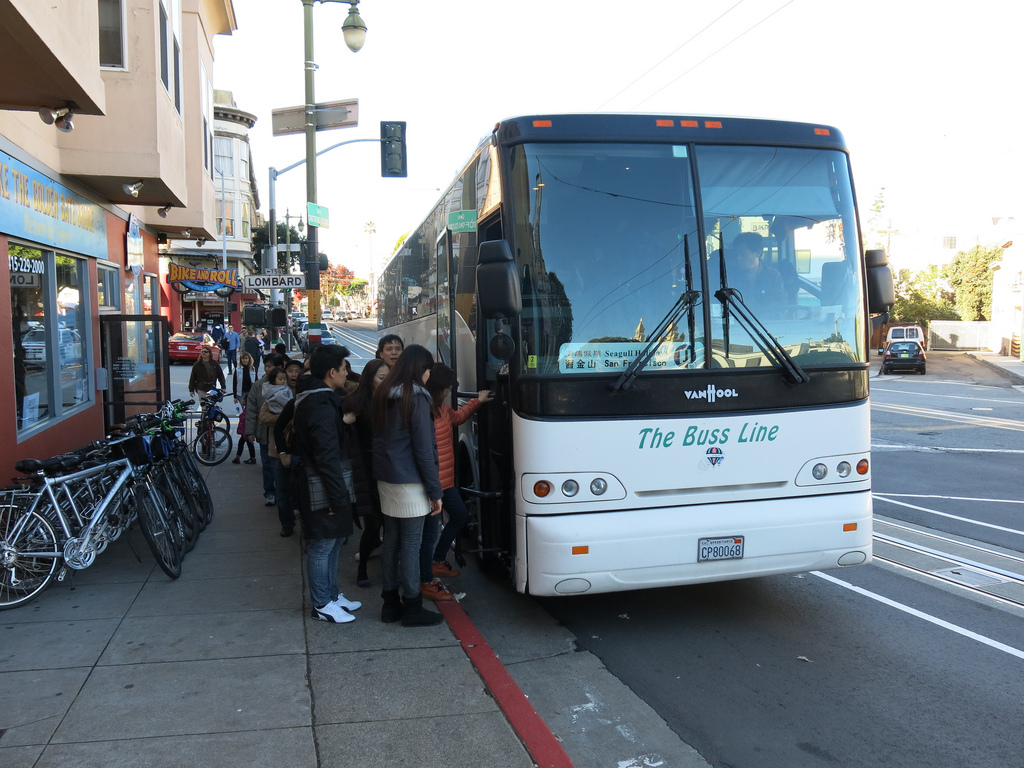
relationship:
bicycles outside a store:
[3, 390, 211, 646] [4, 173, 192, 405]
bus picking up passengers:
[509, 145, 883, 563] [263, 335, 480, 642]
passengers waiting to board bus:
[284, 340, 490, 641] [511, 134, 894, 603]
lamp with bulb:
[327, 1, 384, 45] [340, 31, 369, 55]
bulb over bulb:
[340, 31, 369, 55] [341, 31, 355, 45]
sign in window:
[556, 335, 717, 364] [559, 145, 812, 318]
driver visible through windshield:
[744, 234, 781, 278] [498, 154, 915, 315]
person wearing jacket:
[287, 327, 342, 567] [301, 396, 345, 489]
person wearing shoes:
[287, 327, 342, 567] [307, 600, 350, 626]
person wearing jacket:
[287, 327, 342, 567] [274, 372, 342, 543]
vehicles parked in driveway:
[891, 307, 924, 374] [922, 346, 953, 377]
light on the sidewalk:
[241, 3, 391, 285] [310, 634, 503, 736]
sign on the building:
[18, 191, 112, 252] [8, 113, 177, 416]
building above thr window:
[8, 113, 177, 416] [21, 269, 110, 384]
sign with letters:
[237, 266, 333, 295] [237, 279, 296, 284]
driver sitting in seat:
[727, 234, 770, 278] [675, 243, 712, 313]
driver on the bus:
[727, 234, 770, 278] [423, 132, 882, 599]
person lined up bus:
[287, 327, 342, 567] [376, 96, 897, 634]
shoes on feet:
[307, 575, 370, 632] [311, 586, 400, 643]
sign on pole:
[267, 85, 389, 161] [280, 1, 354, 643]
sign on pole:
[276, 94, 410, 179] [287, 5, 337, 628]